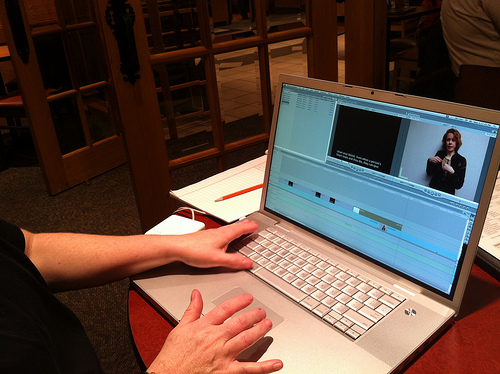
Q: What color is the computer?
A: Grey.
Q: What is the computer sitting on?
A: A table.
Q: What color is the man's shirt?
A: Black.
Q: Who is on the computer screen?
A: A woman.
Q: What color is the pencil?
A: Red.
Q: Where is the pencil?
A: Next to the computer.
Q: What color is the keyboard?
A: Silver.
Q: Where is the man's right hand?
A: On the mousepad.